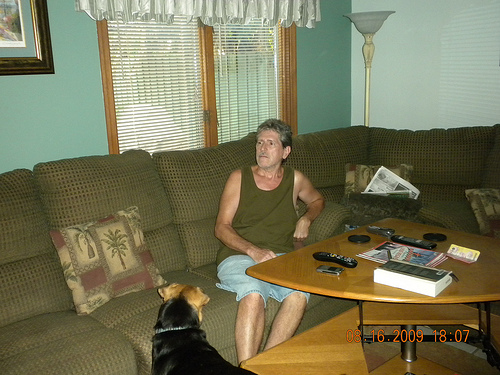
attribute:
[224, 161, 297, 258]
tank top — green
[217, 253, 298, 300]
shorts — denim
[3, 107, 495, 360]
couch — large, brown, sectional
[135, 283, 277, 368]
dog — black, brown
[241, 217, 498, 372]
coffee table — large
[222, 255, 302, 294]
shorts — denim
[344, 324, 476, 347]
numbers — orange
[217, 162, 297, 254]
tank top — green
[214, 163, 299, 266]
top — green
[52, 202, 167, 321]
pillow — tropical themed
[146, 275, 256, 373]
dog — black and brown, black, brown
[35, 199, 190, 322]
pillow — brown, red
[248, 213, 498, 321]
table — wedge shaped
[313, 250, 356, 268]
remote control — black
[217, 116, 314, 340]
man — sitting